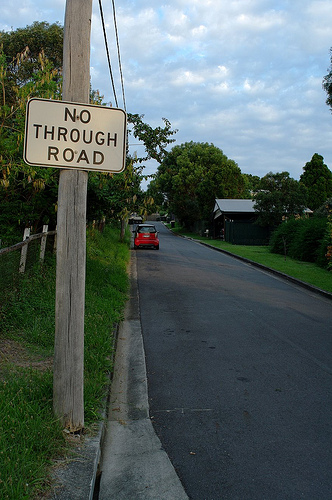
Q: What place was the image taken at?
A: It was taken at the street.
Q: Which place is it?
A: It is a street.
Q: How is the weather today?
A: It is cloudy.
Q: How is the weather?
A: It is cloudy.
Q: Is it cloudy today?
A: Yes, it is cloudy.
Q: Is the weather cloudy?
A: Yes, it is cloudy.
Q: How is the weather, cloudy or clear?
A: It is cloudy.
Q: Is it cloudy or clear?
A: It is cloudy.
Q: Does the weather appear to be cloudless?
A: No, it is cloudy.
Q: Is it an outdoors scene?
A: Yes, it is outdoors.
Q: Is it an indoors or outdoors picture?
A: It is outdoors.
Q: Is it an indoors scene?
A: No, it is outdoors.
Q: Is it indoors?
A: No, it is outdoors.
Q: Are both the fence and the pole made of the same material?
A: Yes, both the fence and the pole are made of wood.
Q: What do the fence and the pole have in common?
A: The material, both the fence and the pole are wooden.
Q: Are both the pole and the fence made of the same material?
A: Yes, both the pole and the fence are made of wood.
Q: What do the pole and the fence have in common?
A: The material, both the pole and the fence are wooden.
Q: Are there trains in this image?
A: No, there are no trains.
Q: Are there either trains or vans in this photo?
A: No, there are no trains or vans.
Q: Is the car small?
A: Yes, the car is small.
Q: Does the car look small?
A: Yes, the car is small.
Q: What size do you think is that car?
A: The car is small.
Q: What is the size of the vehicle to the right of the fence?
A: The car is small.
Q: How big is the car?
A: The car is small.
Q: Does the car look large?
A: No, the car is small.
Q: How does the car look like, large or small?
A: The car is small.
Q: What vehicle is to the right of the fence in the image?
A: The vehicle is a car.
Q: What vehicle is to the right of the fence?
A: The vehicle is a car.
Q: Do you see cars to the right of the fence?
A: Yes, there is a car to the right of the fence.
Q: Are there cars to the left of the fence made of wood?
A: No, the car is to the right of the fence.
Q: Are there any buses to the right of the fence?
A: No, there is a car to the right of the fence.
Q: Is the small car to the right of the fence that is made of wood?
A: Yes, the car is to the right of the fence.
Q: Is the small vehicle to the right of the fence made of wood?
A: Yes, the car is to the right of the fence.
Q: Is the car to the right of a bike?
A: No, the car is to the right of the fence.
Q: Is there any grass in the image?
A: Yes, there is grass.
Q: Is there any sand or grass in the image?
A: Yes, there is grass.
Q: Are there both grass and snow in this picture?
A: No, there is grass but no snow.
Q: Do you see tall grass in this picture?
A: Yes, there is tall grass.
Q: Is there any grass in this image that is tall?
A: Yes, there is grass that is tall.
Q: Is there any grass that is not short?
A: Yes, there is tall grass.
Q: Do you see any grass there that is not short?
A: Yes, there is tall grass.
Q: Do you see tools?
A: No, there are no tools.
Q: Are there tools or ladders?
A: No, there are no tools or ladders.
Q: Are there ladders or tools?
A: No, there are no tools or ladders.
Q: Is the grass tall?
A: Yes, the grass is tall.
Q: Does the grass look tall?
A: Yes, the grass is tall.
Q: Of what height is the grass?
A: The grass is tall.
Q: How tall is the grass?
A: The grass is tall.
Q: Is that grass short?
A: No, the grass is tall.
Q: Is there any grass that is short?
A: No, there is grass but it is tall.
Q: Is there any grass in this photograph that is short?
A: No, there is grass but it is tall.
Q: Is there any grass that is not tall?
A: No, there is grass but it is tall.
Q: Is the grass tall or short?
A: The grass is tall.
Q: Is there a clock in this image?
A: No, there are no clocks.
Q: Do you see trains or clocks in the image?
A: No, there are no clocks or trains.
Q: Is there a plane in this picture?
A: No, there are no airplanes.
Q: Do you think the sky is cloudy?
A: Yes, the sky is cloudy.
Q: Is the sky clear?
A: No, the sky is cloudy.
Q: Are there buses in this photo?
A: No, there are no buses.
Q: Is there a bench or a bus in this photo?
A: No, there are no buses or benches.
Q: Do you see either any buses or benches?
A: No, there are no buses or benches.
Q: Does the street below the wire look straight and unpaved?
A: No, the street is straight but paved.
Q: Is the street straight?
A: Yes, the street is straight.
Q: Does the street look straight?
A: Yes, the street is straight.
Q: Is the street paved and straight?
A: Yes, the street is paved and straight.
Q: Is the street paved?
A: Yes, the street is paved.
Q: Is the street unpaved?
A: No, the street is paved.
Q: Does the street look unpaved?
A: No, the street is paved.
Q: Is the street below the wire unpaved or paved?
A: The street is paved.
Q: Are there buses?
A: No, there are no buses.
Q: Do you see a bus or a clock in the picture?
A: No, there are no buses or clocks.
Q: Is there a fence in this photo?
A: Yes, there is a fence.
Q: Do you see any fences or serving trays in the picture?
A: Yes, there is a fence.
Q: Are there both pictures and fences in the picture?
A: No, there is a fence but no pictures.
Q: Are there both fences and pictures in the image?
A: No, there is a fence but no pictures.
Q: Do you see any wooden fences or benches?
A: Yes, there is a wood fence.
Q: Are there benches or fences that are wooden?
A: Yes, the fence is wooden.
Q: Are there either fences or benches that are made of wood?
A: Yes, the fence is made of wood.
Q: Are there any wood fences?
A: Yes, there is a fence that is made of wood.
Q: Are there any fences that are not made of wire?
A: Yes, there is a fence that is made of wood.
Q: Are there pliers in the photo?
A: No, there are no pliers.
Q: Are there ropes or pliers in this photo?
A: No, there are no pliers or ropes.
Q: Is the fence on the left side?
A: Yes, the fence is on the left of the image.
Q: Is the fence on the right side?
A: No, the fence is on the left of the image.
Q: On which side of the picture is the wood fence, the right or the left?
A: The fence is on the left of the image.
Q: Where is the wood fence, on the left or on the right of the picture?
A: The fence is on the left of the image.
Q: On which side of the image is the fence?
A: The fence is on the left of the image.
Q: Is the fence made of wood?
A: Yes, the fence is made of wood.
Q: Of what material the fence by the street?
A: The fence is made of wood.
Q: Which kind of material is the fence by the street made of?
A: The fence is made of wood.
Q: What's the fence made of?
A: The fence is made of wood.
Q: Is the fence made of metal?
A: No, the fence is made of wood.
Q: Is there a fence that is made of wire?
A: No, there is a fence but it is made of wood.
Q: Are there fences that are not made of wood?
A: No, there is a fence but it is made of wood.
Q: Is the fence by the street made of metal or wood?
A: The fence is made of wood.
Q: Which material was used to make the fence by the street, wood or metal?
A: The fence is made of wood.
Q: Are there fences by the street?
A: Yes, there is a fence by the street.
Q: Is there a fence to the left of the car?
A: Yes, there is a fence to the left of the car.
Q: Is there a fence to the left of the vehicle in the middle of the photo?
A: Yes, there is a fence to the left of the car.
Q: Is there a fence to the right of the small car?
A: No, the fence is to the left of the car.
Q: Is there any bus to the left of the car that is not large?
A: No, there is a fence to the left of the car.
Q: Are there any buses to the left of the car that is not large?
A: No, there is a fence to the left of the car.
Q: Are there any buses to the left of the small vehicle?
A: No, there is a fence to the left of the car.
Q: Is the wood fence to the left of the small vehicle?
A: Yes, the fence is to the left of the car.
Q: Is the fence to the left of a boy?
A: No, the fence is to the left of the car.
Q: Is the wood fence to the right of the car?
A: No, the fence is to the left of the car.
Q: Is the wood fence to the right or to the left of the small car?
A: The fence is to the left of the car.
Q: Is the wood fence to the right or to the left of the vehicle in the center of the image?
A: The fence is to the left of the car.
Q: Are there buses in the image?
A: No, there are no buses.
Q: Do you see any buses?
A: No, there are no buses.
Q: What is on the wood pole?
A: The sign is on the pole.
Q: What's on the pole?
A: The sign is on the pole.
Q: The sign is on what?
A: The sign is on the pole.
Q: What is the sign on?
A: The sign is on the pole.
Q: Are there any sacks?
A: No, there are no sacks.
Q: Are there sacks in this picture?
A: No, there are no sacks.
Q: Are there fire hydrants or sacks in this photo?
A: No, there are no sacks or fire hydrants.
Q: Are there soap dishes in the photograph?
A: No, there are no soap dishes.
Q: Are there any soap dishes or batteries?
A: No, there are no soap dishes or batteries.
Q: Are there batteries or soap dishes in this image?
A: No, there are no soap dishes or batteries.